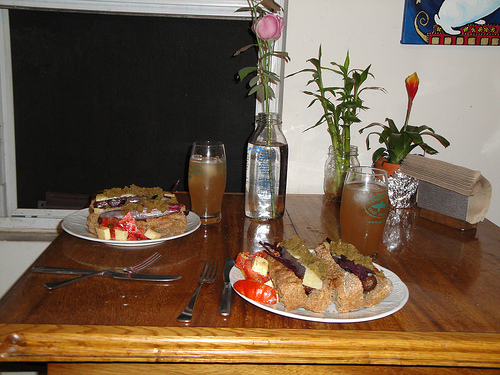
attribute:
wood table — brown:
[42, 168, 486, 356]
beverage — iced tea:
[334, 159, 389, 266]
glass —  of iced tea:
[186, 139, 228, 224]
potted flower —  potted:
[358, 72, 450, 174]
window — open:
[7, 4, 257, 219]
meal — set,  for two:
[226, 235, 411, 322]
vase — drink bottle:
[219, 103, 317, 231]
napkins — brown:
[395, 146, 491, 216]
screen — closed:
[13, 6, 262, 218]